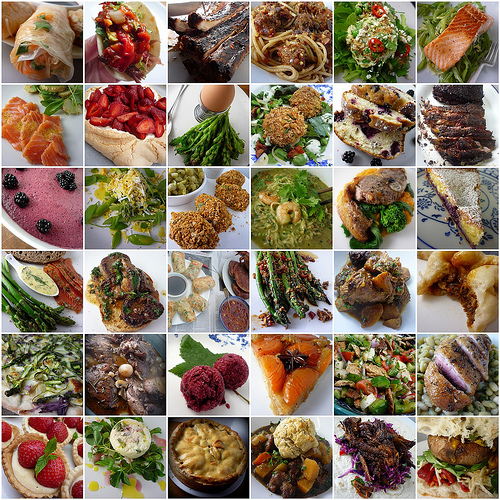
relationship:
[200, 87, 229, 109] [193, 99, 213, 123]
egg in an egg cup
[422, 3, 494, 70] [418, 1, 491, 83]
fish on noodles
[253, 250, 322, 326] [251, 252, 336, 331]
asparagus on white plate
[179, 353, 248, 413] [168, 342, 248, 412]
red berries on plate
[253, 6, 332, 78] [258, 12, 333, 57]
spaghetti and meatballs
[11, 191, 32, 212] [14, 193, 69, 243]
raspberry on top of dessert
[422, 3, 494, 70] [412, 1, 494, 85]
fish on greens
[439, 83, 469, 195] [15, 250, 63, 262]
piece of bread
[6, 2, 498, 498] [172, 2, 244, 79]
picture of meat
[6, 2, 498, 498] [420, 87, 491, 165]
picture of meat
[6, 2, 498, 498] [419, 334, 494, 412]
picture of meat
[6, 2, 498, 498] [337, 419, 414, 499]
picture of meat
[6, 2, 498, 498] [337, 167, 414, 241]
picture of meat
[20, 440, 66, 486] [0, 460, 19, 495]
strawberry on top of tart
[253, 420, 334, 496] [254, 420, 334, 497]
stew in bowl